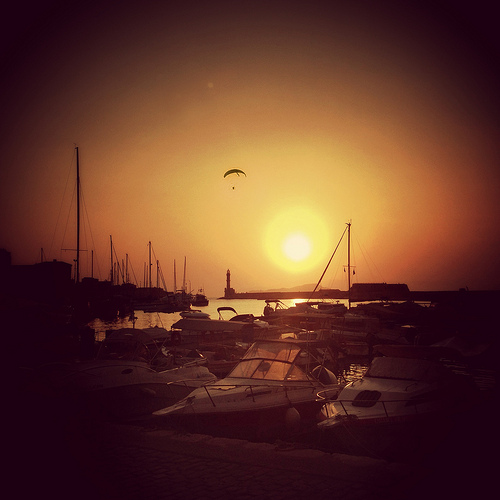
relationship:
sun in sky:
[280, 231, 313, 264] [99, 82, 484, 392]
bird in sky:
[219, 160, 250, 190] [65, 88, 497, 242]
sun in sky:
[272, 211, 333, 273] [103, 96, 498, 225]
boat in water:
[129, 280, 196, 319] [140, 307, 177, 327]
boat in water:
[191, 286, 213, 307] [212, 289, 253, 311]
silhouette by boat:
[314, 213, 371, 315] [313, 352, 475, 436]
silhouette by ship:
[114, 251, 134, 293] [117, 247, 149, 310]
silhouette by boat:
[112, 260, 121, 289] [149, 339, 349, 420]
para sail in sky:
[217, 160, 254, 196] [272, 129, 408, 239]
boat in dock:
[313, 352, 475, 436] [66, 370, 480, 470]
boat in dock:
[150, 307, 351, 425] [15, 411, 484, 468]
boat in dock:
[66, 338, 225, 407] [15, 403, 448, 492]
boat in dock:
[171, 316, 255, 336] [39, 396, 480, 478]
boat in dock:
[330, 305, 384, 361] [32, 355, 477, 486]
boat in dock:
[313, 352, 475, 436] [23, 347, 483, 488]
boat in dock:
[174, 301, 264, 356] [21, 305, 479, 475]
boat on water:
[149, 339, 349, 420] [225, 295, 255, 308]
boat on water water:
[179, 307, 211, 318] [232, 294, 261, 316]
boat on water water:
[179, 307, 211, 318] [236, 293, 255, 310]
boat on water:
[192, 283, 210, 307] [241, 296, 261, 317]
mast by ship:
[104, 233, 119, 288] [93, 284, 133, 318]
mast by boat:
[178, 258, 192, 301] [192, 283, 210, 307]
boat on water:
[257, 217, 393, 324] [217, 288, 413, 318]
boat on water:
[179, 307, 211, 318] [135, 295, 235, 318]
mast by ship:
[75, 242, 99, 294] [83, 230, 148, 320]